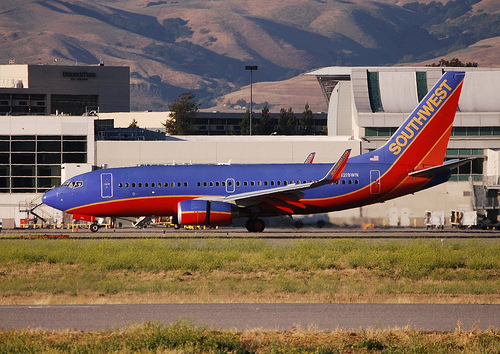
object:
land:
[0, 228, 499, 354]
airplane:
[40, 71, 479, 234]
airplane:
[40, 71, 485, 234]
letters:
[386, 143, 401, 156]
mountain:
[306, 5, 442, 64]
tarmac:
[0, 304, 498, 332]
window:
[73, 181, 82, 189]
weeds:
[353, 237, 428, 262]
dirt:
[71, 240, 354, 298]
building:
[0, 59, 131, 113]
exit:
[368, 169, 381, 196]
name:
[386, 78, 451, 155]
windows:
[352, 179, 359, 185]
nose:
[39, 185, 59, 211]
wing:
[191, 149, 353, 203]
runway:
[0, 223, 498, 238]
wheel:
[88, 224, 100, 233]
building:
[0, 114, 95, 228]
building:
[88, 112, 326, 136]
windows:
[117, 181, 124, 188]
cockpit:
[54, 168, 110, 203]